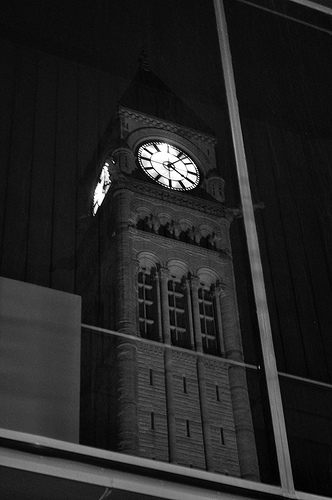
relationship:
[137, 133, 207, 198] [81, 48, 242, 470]
clock on tower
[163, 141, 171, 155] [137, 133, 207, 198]
number on clock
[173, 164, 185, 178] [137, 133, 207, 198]
hand on clock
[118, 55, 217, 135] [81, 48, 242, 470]
roof on tower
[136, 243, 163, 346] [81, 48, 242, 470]
window on tower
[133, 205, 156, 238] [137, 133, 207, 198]
arch on clock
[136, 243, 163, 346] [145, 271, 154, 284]
window has pane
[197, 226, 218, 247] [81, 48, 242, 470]
opening in tower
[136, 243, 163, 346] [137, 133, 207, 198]
window under clock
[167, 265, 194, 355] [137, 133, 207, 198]
window under clock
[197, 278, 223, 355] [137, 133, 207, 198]
window under clock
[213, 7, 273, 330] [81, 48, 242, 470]
pole in front of tower